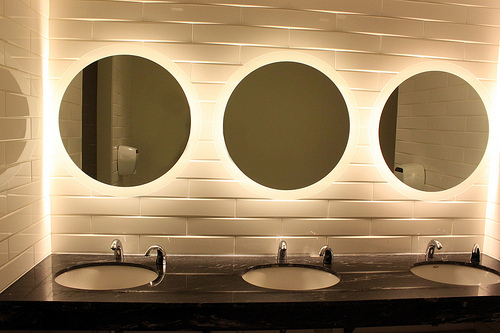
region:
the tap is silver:
[240, 230, 360, 285]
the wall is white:
[187, 211, 363, 236]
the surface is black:
[355, 263, 402, 295]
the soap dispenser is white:
[112, 143, 149, 175]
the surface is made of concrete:
[359, 278, 401, 312]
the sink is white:
[268, 266, 323, 286]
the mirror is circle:
[229, 76, 359, 183]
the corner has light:
[31, 86, 73, 254]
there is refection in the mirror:
[100, 118, 164, 172]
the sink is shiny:
[264, 274, 316, 281]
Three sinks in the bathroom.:
[55, 224, 488, 307]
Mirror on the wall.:
[221, 50, 358, 208]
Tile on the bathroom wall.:
[164, 159, 258, 224]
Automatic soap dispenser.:
[315, 234, 353, 279]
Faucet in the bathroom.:
[260, 224, 305, 274]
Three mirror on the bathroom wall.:
[59, 36, 499, 331]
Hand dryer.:
[113, 117, 159, 189]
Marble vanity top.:
[33, 280, 473, 298]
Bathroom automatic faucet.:
[192, 228, 419, 329]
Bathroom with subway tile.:
[60, 24, 399, 305]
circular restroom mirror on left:
[54, 40, 201, 200]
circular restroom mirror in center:
[213, 49, 358, 201]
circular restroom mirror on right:
[366, 55, 498, 205]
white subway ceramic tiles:
[0, 1, 499, 294]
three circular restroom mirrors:
[51, 40, 498, 200]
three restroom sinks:
[50, 237, 499, 297]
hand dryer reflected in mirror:
[113, 142, 141, 179]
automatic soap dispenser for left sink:
[144, 242, 169, 266]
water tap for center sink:
[276, 238, 293, 263]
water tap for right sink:
[423, 235, 443, 263]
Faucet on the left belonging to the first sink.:
[109, 235, 130, 260]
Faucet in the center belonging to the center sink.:
[266, 233, 293, 263]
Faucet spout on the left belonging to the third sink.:
[425, 237, 445, 259]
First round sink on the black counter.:
[53, 264, 160, 289]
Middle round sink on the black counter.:
[234, 258, 343, 298]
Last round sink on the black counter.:
[405, 257, 499, 293]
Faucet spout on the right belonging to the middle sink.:
[314, 243, 341, 270]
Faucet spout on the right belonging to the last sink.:
[468, 237, 489, 269]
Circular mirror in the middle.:
[215, 42, 360, 204]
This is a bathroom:
[47, 31, 492, 315]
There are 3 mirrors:
[61, 62, 487, 213]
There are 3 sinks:
[46, 239, 498, 312]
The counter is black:
[39, 249, 474, 317]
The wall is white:
[94, 7, 451, 253]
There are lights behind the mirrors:
[27, 33, 493, 249]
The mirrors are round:
[67, 49, 469, 223]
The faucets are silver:
[91, 230, 491, 262]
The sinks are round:
[69, 241, 496, 296]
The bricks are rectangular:
[62, 7, 451, 77]